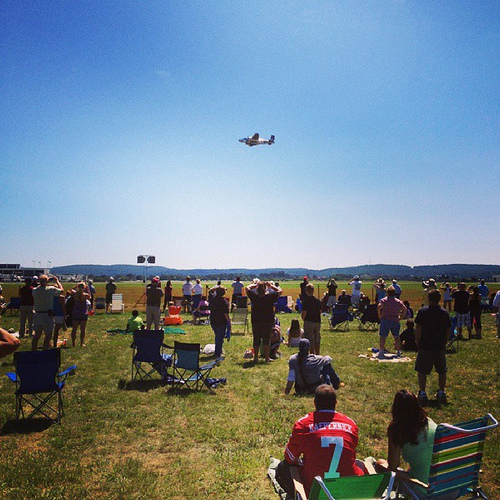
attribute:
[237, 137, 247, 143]
nose — flying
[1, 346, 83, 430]
chair — blue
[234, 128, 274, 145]
plane — flying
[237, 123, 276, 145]
plane — flying